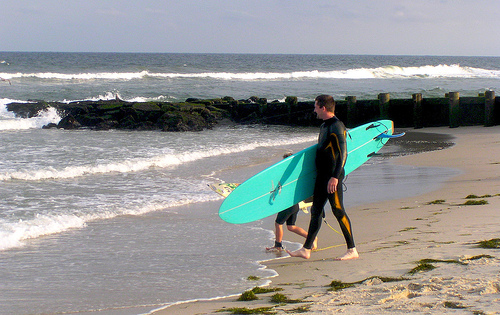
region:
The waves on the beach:
[26, 145, 164, 244]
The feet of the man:
[283, 230, 365, 262]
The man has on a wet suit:
[300, 119, 370, 254]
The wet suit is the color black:
[301, 120, 368, 255]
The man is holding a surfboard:
[193, 93, 420, 268]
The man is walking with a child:
[237, 81, 380, 268]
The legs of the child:
[266, 210, 319, 256]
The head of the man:
[308, 90, 343, 127]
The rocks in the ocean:
[11, 82, 231, 144]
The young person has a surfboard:
[201, 169, 320, 214]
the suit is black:
[318, 124, 349, 164]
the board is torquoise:
[246, 194, 271, 212]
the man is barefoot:
[291, 244, 318, 260]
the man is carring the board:
[304, 91, 348, 163]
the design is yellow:
[335, 209, 355, 239]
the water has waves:
[70, 60, 117, 85]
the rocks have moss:
[155, 96, 199, 123]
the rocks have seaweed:
[156, 100, 195, 119]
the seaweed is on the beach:
[326, 272, 371, 299]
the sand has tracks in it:
[388, 277, 443, 313]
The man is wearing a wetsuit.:
[281, 75, 361, 270]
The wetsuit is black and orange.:
[280, 86, 360, 271]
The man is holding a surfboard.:
[200, 75, 405, 275]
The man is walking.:
[205, 61, 407, 281]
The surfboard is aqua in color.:
[212, 85, 404, 275]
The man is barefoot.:
[208, 60, 408, 282]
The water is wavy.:
[0, 48, 499, 313]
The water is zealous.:
[0, 46, 499, 312]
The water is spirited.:
[1, 43, 498, 313]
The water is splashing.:
[0, 42, 498, 313]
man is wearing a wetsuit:
[294, 82, 382, 297]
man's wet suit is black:
[302, 108, 385, 263]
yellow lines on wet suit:
[317, 111, 364, 248]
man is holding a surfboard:
[174, 101, 462, 279]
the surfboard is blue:
[202, 110, 412, 228]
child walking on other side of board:
[247, 147, 309, 252]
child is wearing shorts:
[265, 204, 311, 234]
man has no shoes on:
[286, 243, 370, 273]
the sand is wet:
[62, 111, 479, 296]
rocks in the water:
[6, 81, 497, 143]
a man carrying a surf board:
[236, 74, 365, 289]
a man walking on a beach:
[278, 94, 353, 284]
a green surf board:
[200, 118, 402, 243]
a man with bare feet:
[285, 185, 350, 278]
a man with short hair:
[308, 92, 348, 123]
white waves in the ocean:
[3, 55, 486, 105]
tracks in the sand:
[301, 267, 488, 314]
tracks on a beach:
[301, 239, 498, 314]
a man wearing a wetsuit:
[297, 94, 345, 273]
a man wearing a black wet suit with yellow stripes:
[286, 101, 347, 275]